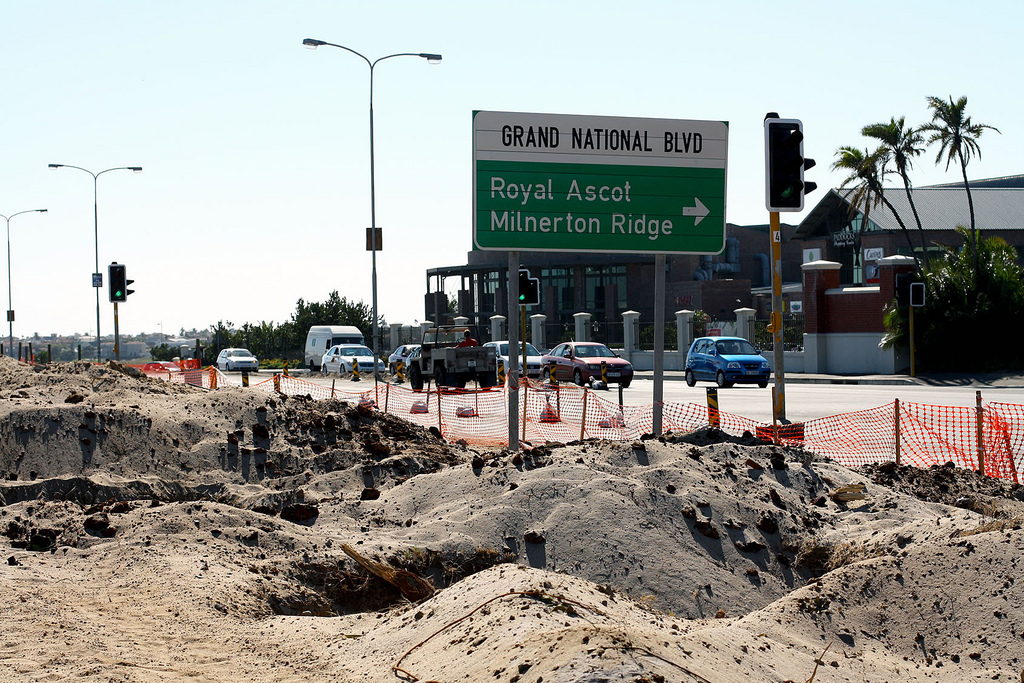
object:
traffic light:
[762, 112, 816, 212]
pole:
[766, 212, 786, 420]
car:
[684, 335, 771, 388]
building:
[785, 187, 1024, 375]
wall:
[799, 234, 916, 374]